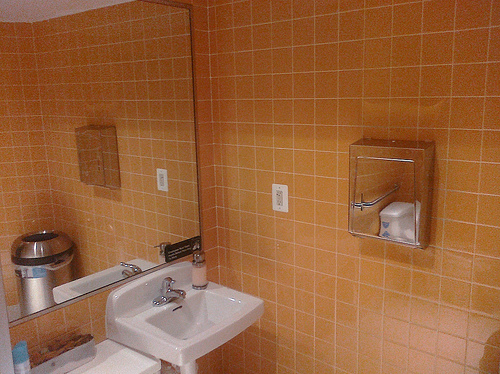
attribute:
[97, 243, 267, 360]
sink — White ceramic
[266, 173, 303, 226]
outlet — white  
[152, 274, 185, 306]
faucet — silver 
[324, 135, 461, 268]
dispenser — towel , Reflection  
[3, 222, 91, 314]
trash can — metallic, trash 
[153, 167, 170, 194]
outlet — white power 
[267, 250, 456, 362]
tile — orange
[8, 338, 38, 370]
can — air freshener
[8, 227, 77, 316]
waste bin — waste , corner, metal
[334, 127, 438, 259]
container — metallic  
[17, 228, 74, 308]
trash can — Large metal trash 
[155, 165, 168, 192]
socket — electric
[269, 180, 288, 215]
socket — electric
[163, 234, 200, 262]
black sign — black 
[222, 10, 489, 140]
wall — tiled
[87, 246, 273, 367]
sink — edge 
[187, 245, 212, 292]
soap — dispenser 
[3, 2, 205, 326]
mirror — large shiny, above 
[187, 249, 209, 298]
soap — liquid 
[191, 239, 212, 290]
soap — Hand 